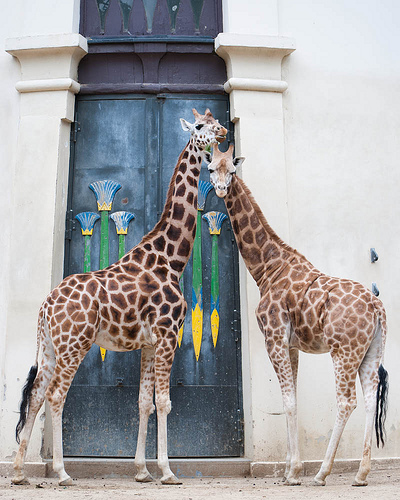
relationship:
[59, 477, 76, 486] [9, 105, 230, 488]
hoof of giraffe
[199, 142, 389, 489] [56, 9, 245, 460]
giraffe in front of door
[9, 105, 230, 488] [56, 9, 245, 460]
giraffe in front of door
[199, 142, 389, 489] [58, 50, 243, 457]
giraffe standing door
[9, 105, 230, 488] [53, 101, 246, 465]
giraffe in front of door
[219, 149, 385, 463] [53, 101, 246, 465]
giraffe in front of door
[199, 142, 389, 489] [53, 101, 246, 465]
giraffe in front of door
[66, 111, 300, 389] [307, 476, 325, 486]
giraffe has hoof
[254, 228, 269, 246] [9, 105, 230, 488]
brown spot on giraffe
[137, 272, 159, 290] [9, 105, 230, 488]
brown spot on giraffe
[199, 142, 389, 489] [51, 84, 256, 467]
giraffe near door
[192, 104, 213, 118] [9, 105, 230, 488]
horns on giraffe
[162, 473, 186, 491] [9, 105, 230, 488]
hoof of giraffe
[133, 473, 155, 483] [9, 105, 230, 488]
hoof of giraffe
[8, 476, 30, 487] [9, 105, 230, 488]
hoof of giraffe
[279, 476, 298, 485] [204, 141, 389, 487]
hoof of giraffe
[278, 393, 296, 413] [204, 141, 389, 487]
knee of giraffe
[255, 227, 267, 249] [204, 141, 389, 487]
brown spot on giraffe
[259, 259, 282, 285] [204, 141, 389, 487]
spot on giraffe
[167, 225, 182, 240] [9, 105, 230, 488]
spot on giraffe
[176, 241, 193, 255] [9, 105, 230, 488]
spot on giraffe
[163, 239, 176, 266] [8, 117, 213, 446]
spot on giraffe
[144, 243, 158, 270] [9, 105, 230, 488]
spot on giraffe